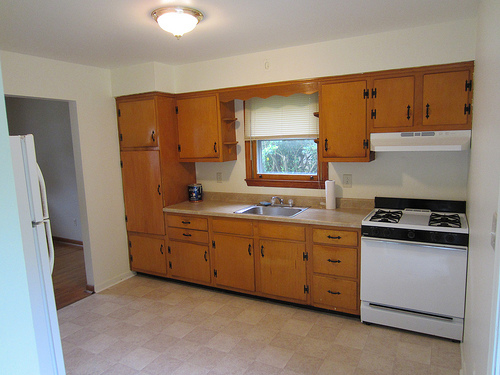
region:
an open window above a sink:
[240, 103, 321, 188]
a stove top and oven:
[360, 133, 470, 337]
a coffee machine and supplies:
[183, 178, 208, 203]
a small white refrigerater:
[0, 130, 61, 370]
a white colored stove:
[358, 193, 468, 342]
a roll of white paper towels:
[321, 176, 338, 211]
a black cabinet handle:
[148, 129, 156, 145]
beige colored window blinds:
[241, 88, 321, 141]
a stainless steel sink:
[230, 193, 307, 223]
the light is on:
[151, 7, 199, 39]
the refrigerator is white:
[8, 129, 70, 374]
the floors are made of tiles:
[63, 274, 460, 372]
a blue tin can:
[185, 178, 203, 204]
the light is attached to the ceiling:
[150, 7, 202, 39]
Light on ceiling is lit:
[152, 6, 203, 43]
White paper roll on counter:
[325, 177, 335, 209]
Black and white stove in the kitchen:
[358, 194, 467, 342]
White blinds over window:
[244, 87, 317, 133]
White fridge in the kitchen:
[9, 133, 65, 373]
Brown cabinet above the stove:
[320, 76, 373, 159]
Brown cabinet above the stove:
[368, 68, 416, 127]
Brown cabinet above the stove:
[417, 60, 469, 126]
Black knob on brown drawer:
[326, 230, 342, 240]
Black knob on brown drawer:
[323, 258, 342, 266]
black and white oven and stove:
[358, 195, 470, 342]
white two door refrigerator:
[6, 130, 69, 373]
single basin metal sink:
[235, 193, 309, 222]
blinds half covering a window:
[243, 88, 323, 181]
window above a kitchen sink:
[236, 91, 321, 221]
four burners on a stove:
[369, 205, 461, 231]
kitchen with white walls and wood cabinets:
[1, 0, 498, 371]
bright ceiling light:
[150, 5, 205, 43]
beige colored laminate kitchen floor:
[53, 274, 465, 374]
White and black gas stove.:
[356, 190, 479, 332]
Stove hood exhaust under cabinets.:
[369, 118, 477, 160]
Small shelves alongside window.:
[221, 102, 330, 155]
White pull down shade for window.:
[240, 94, 322, 189]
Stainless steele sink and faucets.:
[233, 185, 315, 236]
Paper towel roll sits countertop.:
[322, 174, 338, 219]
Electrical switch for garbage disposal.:
[340, 167, 355, 193]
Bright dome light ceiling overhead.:
[127, 3, 232, 55]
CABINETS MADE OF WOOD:
[333, 93, 349, 130]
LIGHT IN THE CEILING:
[148, 5, 207, 35]